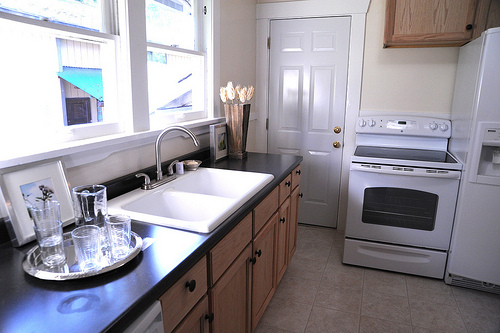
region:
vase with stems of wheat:
[218, 81, 255, 159]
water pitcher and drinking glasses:
[19, 184, 139, 267]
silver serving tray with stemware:
[17, 221, 144, 283]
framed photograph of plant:
[2, 155, 80, 246]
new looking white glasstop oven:
[335, 111, 456, 282]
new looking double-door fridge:
[445, 25, 496, 293]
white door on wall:
[262, 16, 343, 230]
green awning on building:
[55, 57, 106, 113]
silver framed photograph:
[210, 121, 232, 161]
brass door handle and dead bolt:
[333, 124, 341, 149]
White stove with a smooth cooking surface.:
[344, 103, 454, 284]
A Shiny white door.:
[263, 13, 345, 233]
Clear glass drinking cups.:
[25, 182, 138, 269]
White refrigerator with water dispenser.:
[451, 24, 498, 328]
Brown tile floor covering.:
[294, 267, 431, 331]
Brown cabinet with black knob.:
[206, 249, 261, 331]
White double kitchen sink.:
[123, 160, 272, 230]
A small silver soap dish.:
[179, 155, 204, 175]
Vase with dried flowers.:
[219, 77, 261, 167]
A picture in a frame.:
[206, 121, 233, 164]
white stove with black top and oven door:
[335, 112, 470, 287]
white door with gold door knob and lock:
[261, 12, 355, 234]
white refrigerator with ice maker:
[438, 26, 496, 303]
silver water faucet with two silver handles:
[132, 123, 202, 193]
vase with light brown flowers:
[216, 76, 257, 161]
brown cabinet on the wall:
[378, 2, 487, 51]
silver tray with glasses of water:
[18, 182, 145, 288]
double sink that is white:
[83, 162, 278, 240]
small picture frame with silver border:
[206, 121, 232, 163]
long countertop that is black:
[1, 144, 309, 331]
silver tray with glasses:
[18, 225, 145, 282]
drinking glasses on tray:
[28, 182, 133, 269]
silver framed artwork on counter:
[3, 155, 81, 243]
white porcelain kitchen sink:
[96, 160, 275, 241]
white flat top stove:
[340, 112, 458, 282]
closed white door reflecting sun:
[269, 41, 346, 228]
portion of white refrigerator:
[446, 26, 498, 301]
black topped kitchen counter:
[3, 147, 301, 332]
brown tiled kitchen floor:
[283, 258, 498, 331]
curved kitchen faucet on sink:
[133, 123, 203, 188]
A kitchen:
[29, 42, 472, 321]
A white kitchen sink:
[98, 111, 276, 242]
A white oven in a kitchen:
[345, 110, 476, 307]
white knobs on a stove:
[349, 107, 463, 167]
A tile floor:
[278, 255, 404, 323]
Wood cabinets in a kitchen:
[174, 225, 296, 312]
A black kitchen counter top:
[6, 241, 164, 330]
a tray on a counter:
[6, 199, 152, 292]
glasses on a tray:
[23, 190, 144, 287]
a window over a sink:
[60, 30, 234, 192]